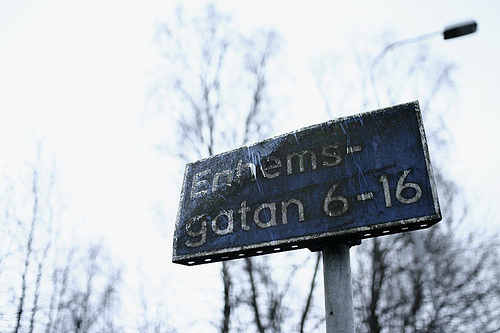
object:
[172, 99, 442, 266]
sign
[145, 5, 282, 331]
tree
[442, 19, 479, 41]
light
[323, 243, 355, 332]
pole